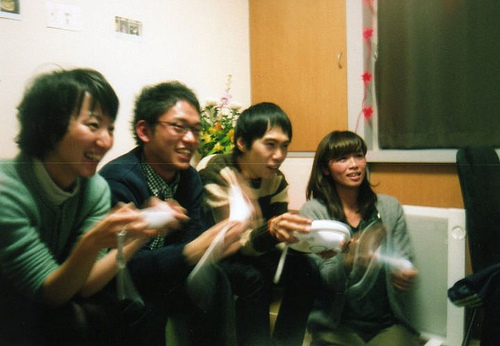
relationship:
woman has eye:
[295, 131, 416, 346] [352, 153, 365, 162]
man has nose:
[200, 98, 321, 344] [272, 145, 288, 163]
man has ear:
[200, 98, 321, 344] [233, 131, 256, 157]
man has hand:
[200, 98, 321, 344] [273, 210, 313, 249]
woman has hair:
[295, 131, 416, 346] [306, 124, 382, 227]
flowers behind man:
[195, 75, 253, 169] [200, 98, 321, 344]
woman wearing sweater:
[295, 131, 416, 346] [297, 187, 421, 336]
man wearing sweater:
[200, 98, 321, 344] [195, 152, 304, 260]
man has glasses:
[97, 73, 269, 340] [152, 117, 205, 140]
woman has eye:
[295, 131, 416, 346] [334, 153, 350, 166]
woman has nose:
[295, 131, 416, 346] [347, 154, 358, 172]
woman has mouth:
[295, 131, 416, 346] [346, 172, 363, 182]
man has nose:
[97, 73, 269, 340] [181, 125, 197, 148]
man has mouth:
[200, 98, 321, 344] [267, 161, 285, 177]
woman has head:
[295, 131, 416, 346] [310, 129, 372, 198]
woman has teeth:
[295, 131, 416, 346] [350, 170, 362, 177]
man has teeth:
[200, 98, 321, 344] [268, 162, 283, 171]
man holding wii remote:
[97, 73, 269, 340] [224, 181, 257, 235]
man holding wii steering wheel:
[200, 98, 321, 344] [280, 212, 356, 263]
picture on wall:
[110, 9, 146, 41] [5, 0, 253, 187]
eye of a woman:
[352, 153, 365, 162] [295, 131, 416, 346]